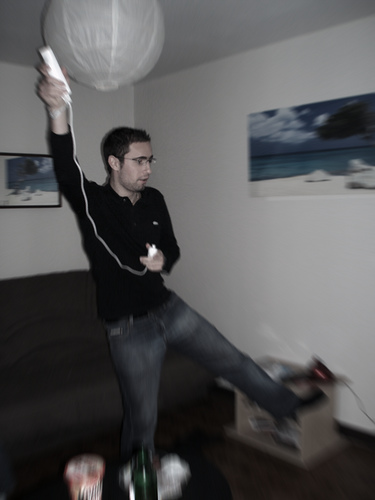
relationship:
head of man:
[87, 109, 175, 203] [34, 63, 329, 493]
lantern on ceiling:
[36, 3, 172, 97] [2, 0, 373, 86]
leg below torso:
[165, 292, 328, 422] [59, 104, 245, 402]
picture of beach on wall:
[243, 91, 374, 200] [126, 14, 373, 429]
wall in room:
[126, 14, 373, 429] [2, 1, 373, 496]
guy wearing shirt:
[36, 62, 318, 461] [43, 123, 180, 321]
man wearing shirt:
[34, 63, 329, 493] [43, 123, 180, 321]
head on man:
[87, 109, 175, 203] [34, 63, 329, 493]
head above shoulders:
[87, 109, 175, 203] [61, 178, 177, 221]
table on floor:
[245, 349, 306, 441] [7, 285, 352, 499]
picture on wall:
[243, 91, 374, 200] [126, 14, 373, 429]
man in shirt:
[34, 63, 329, 493] [51, 132, 171, 307]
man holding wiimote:
[34, 63, 329, 493] [35, 46, 77, 112]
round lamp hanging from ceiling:
[39, 0, 170, 89] [139, 2, 374, 82]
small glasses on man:
[109, 147, 164, 169] [23, 99, 350, 453]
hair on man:
[98, 125, 150, 169] [34, 63, 329, 493]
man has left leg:
[34, 63, 329, 493] [175, 301, 340, 436]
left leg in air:
[175, 301, 340, 436] [196, 289, 333, 439]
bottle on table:
[132, 440, 154, 496] [49, 439, 231, 498]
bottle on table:
[132, 440, 154, 496] [26, 453, 258, 498]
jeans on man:
[87, 289, 316, 486] [76, 128, 269, 466]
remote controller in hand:
[40, 46, 158, 275] [37, 63, 65, 115]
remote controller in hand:
[40, 46, 158, 275] [140, 241, 164, 269]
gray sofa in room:
[12, 273, 215, 457] [12, 116, 363, 491]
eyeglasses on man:
[115, 155, 157, 165] [84, 124, 211, 449]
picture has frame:
[1, 151, 65, 209] [0, 153, 61, 207]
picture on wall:
[1, 151, 65, 209] [0, 58, 132, 281]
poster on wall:
[245, 89, 374, 197] [181, 81, 363, 243]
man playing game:
[34, 63, 329, 493] [40, 43, 160, 275]